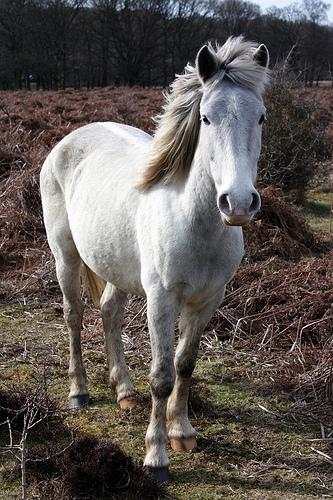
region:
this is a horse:
[26, 29, 283, 371]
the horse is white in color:
[14, 58, 278, 487]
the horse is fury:
[154, 92, 196, 178]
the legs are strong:
[141, 291, 207, 463]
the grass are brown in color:
[248, 251, 308, 355]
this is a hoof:
[176, 431, 195, 450]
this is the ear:
[193, 45, 221, 84]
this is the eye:
[196, 113, 215, 127]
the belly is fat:
[77, 189, 136, 259]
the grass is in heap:
[45, 88, 90, 120]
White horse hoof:
[170, 436, 198, 451]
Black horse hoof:
[143, 466, 174, 485]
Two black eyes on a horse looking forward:
[201, 112, 267, 128]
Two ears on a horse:
[194, 44, 270, 80]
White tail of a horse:
[81, 263, 107, 309]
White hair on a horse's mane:
[135, 38, 265, 195]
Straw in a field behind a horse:
[2, 85, 329, 134]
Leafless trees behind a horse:
[1, 1, 332, 86]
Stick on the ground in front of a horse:
[5, 404, 74, 497]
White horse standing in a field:
[34, 35, 271, 485]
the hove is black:
[69, 391, 105, 413]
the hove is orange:
[177, 432, 208, 454]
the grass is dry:
[259, 289, 317, 393]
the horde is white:
[43, 25, 260, 428]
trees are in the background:
[22, 14, 158, 80]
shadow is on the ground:
[219, 439, 315, 495]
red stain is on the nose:
[226, 207, 255, 218]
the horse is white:
[43, 53, 262, 470]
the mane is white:
[173, 90, 188, 159]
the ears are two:
[193, 36, 289, 81]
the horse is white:
[31, 57, 286, 464]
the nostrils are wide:
[202, 174, 260, 241]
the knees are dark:
[133, 348, 206, 403]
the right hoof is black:
[135, 454, 181, 492]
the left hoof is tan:
[164, 428, 215, 456]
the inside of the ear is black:
[186, 41, 223, 87]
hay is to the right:
[241, 270, 323, 379]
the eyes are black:
[162, 97, 276, 131]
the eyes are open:
[176, 95, 274, 135]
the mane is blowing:
[138, 17, 268, 191]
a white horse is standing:
[36, 32, 290, 489]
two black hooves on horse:
[66, 383, 180, 492]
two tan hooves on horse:
[117, 390, 200, 458]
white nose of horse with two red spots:
[214, 172, 262, 241]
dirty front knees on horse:
[139, 341, 202, 416]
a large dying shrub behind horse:
[222, 56, 329, 234]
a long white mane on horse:
[111, 30, 277, 204]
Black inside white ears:
[192, 42, 274, 96]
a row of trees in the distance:
[11, 3, 332, 103]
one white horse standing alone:
[30, 32, 293, 444]